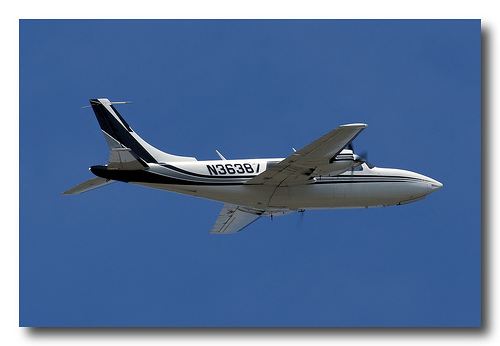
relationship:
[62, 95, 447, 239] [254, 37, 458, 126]
plane in sky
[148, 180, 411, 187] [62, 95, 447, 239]
stripe on plane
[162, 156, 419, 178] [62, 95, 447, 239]
stripe on plane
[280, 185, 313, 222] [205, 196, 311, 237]
engine on wing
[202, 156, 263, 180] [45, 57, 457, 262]
number on plane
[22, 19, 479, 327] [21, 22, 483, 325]
clouds in sky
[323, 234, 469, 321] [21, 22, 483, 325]
clouds sky in sky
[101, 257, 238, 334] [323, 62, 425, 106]
clouds in sky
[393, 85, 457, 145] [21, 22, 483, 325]
clouds in sky